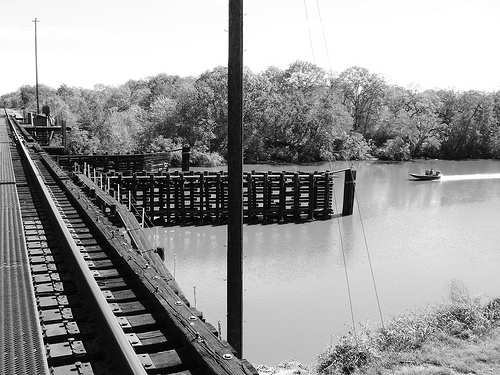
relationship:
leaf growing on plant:
[163, 81, 179, 92] [150, 73, 205, 163]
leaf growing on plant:
[208, 70, 246, 111] [196, 63, 258, 176]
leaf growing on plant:
[133, 84, 152, 104] [150, 82, 216, 171]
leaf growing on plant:
[267, 90, 286, 117] [260, 73, 308, 163]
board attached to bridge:
[137, 340, 199, 370] [3, 106, 223, 373]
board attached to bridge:
[136, 327, 169, 347] [3, 106, 223, 373]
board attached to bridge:
[101, 292, 171, 322] [3, 106, 223, 373]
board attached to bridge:
[136, 327, 169, 347] [13, 110, 204, 373]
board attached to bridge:
[36, 328, 100, 360] [3, 106, 223, 373]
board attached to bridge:
[25, 311, 98, 343] [2, 103, 253, 371]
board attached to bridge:
[22, 298, 100, 327] [2, 103, 253, 371]